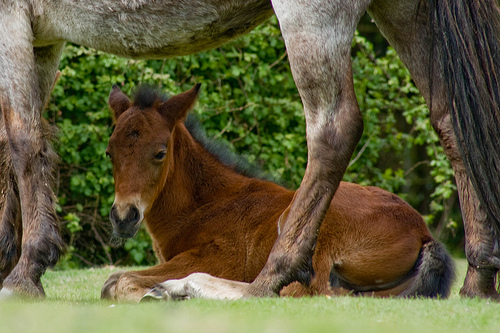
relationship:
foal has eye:
[100, 83, 456, 301] [150, 145, 170, 164]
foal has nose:
[100, 83, 456, 301] [104, 189, 155, 239]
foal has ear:
[100, 83, 456, 301] [156, 71, 209, 136]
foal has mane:
[100, 83, 456, 301] [135, 71, 266, 177]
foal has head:
[100, 83, 456, 301] [94, 77, 204, 237]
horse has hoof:
[3, 5, 484, 305] [256, 250, 325, 304]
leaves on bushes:
[231, 95, 296, 131] [42, 11, 468, 263]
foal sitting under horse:
[100, 83, 456, 301] [0, 0, 499, 303]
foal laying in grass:
[100, 83, 456, 301] [1, 259, 498, 329]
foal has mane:
[100, 83, 456, 301] [135, 70, 284, 192]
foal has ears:
[100, 83, 456, 301] [104, 82, 201, 117]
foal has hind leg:
[100, 83, 456, 301] [165, 238, 416, 292]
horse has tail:
[3, 5, 484, 305] [423, 5, 498, 237]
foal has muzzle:
[59, 82, 464, 307] [96, 167, 156, 239]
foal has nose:
[100, 83, 456, 301] [105, 201, 145, 237]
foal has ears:
[100, 83, 456, 301] [101, 81, 201, 122]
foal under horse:
[100, 83, 456, 301] [0, 0, 499, 303]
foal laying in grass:
[100, 83, 456, 301] [4, 265, 498, 330]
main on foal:
[133, 78, 273, 184] [100, 83, 456, 301]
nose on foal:
[108, 205, 140, 231] [100, 83, 456, 301]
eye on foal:
[149, 150, 170, 161] [100, 83, 456, 301]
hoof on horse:
[0, 268, 50, 302] [3, 5, 484, 305]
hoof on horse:
[245, 260, 308, 298] [3, 5, 484, 305]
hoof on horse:
[456, 262, 498, 299] [3, 5, 484, 305]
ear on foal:
[159, 82, 201, 122] [100, 83, 456, 301]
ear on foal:
[108, 82, 128, 120] [100, 83, 456, 301]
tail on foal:
[402, 238, 456, 298] [100, 83, 456, 301]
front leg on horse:
[0, 4, 57, 279] [3, 5, 484, 305]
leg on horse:
[1, 161, 20, 277] [3, 5, 484, 305]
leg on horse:
[267, 0, 370, 282] [3, 5, 484, 305]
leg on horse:
[362, 0, 498, 275] [3, 5, 484, 305]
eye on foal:
[153, 148, 170, 163] [100, 83, 456, 301]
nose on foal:
[108, 205, 140, 222] [100, 83, 456, 301]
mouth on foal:
[107, 212, 143, 237] [100, 83, 456, 301]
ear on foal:
[159, 79, 200, 126] [100, 83, 456, 301]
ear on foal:
[104, 82, 129, 120] [100, 83, 456, 301]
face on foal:
[102, 99, 186, 240] [100, 83, 456, 301]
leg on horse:
[0, 115, 20, 277] [3, 5, 484, 305]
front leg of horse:
[0, 0, 68, 279] [3, 5, 484, 305]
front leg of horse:
[0, 4, 57, 279] [3, 5, 484, 305]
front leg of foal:
[104, 245, 207, 302] [100, 83, 456, 301]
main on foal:
[126, 76, 267, 177] [100, 83, 456, 301]